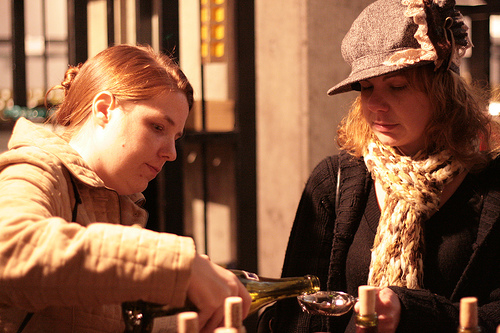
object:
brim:
[325, 52, 420, 96]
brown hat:
[326, 0, 468, 96]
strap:
[68, 182, 82, 221]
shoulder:
[6, 147, 74, 179]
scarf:
[361, 133, 477, 293]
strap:
[330, 151, 345, 264]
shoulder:
[281, 148, 373, 282]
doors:
[1, 0, 256, 270]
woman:
[1, 43, 252, 333]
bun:
[60, 66, 79, 88]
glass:
[296, 290, 355, 317]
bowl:
[297, 291, 355, 317]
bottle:
[123, 272, 320, 332]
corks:
[176, 285, 478, 333]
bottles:
[356, 285, 481, 332]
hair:
[46, 43, 194, 128]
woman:
[272, 0, 499, 331]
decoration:
[406, 0, 472, 63]